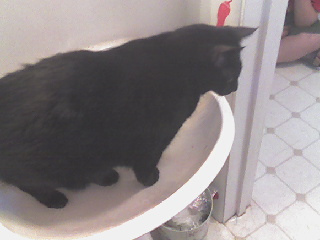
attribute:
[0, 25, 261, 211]
cat — furry, black, looking, overweight, standing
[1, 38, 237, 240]
sink — white, oval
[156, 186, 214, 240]
bin — garbage, trash, metal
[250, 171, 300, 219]
tile — square, linoleum, pink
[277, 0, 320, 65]
chair — green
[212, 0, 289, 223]
jam — grey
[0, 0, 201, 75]
wall — white